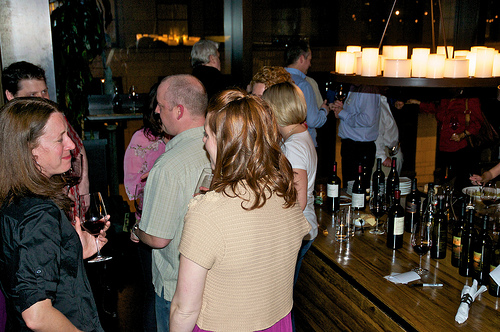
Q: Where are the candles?
A: Chandelier.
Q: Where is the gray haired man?
A: Back wall.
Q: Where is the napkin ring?
A: Around napkin on bar.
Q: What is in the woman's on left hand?
A: Glass of red wine.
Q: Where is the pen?
A: Om bar.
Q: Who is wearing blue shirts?
A: Men in background.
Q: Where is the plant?
A: Left wall in background.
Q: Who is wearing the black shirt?
A: Woman on left.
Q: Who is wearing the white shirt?
A: Blonde woman near bar.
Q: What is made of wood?
A: The bar.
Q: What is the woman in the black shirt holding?
A: A wine glass?.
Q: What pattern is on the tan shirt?
A: Horizontal stripes.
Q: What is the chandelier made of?
A: A group of candles.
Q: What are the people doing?
A: Drinking wine.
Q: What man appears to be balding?
A: The man in the short sleeve shirt.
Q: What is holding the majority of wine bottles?
A: A brown wood table.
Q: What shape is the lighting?
A: Circular.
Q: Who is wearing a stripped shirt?
A: A woman in a bar.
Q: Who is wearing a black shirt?
A: A woman in a bar talking to a woman in a stripped shirt.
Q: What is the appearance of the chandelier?
A: Illuminated with candles.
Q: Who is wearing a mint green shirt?
A: A man in a bar.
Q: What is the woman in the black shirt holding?
A: A glass of wine.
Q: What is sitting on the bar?
A: Bottles and glasses.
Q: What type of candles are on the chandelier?
A: Faux candles.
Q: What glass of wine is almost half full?
A: The wine glass the girl in black is holding.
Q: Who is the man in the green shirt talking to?
A: Another man.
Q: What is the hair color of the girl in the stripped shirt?
A: Brown.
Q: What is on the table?
A: Beer bottles.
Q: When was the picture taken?
A: Night time.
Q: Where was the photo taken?
A: In a bar.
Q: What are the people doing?
A: Drinking.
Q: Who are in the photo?
A: People.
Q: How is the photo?
A: Clear.